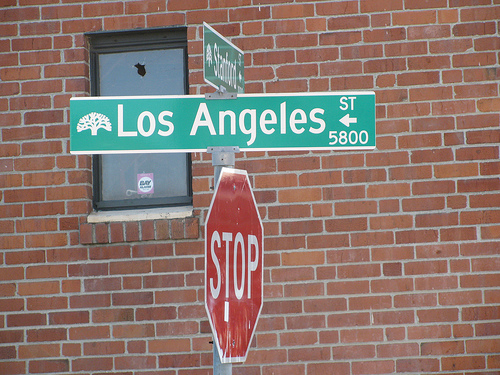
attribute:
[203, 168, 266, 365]
sign — stop, for stopping, red, angled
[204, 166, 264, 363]
stop sign — red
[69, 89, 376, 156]
sign — street, green, angled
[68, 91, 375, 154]
street sign — green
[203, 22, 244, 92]
sign — street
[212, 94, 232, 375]
pole — metal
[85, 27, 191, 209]
window — white, glass, opaque, broken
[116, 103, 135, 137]
letter — white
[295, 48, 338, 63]
brick — red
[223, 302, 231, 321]
sticker — white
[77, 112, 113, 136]
tree — stamped, white